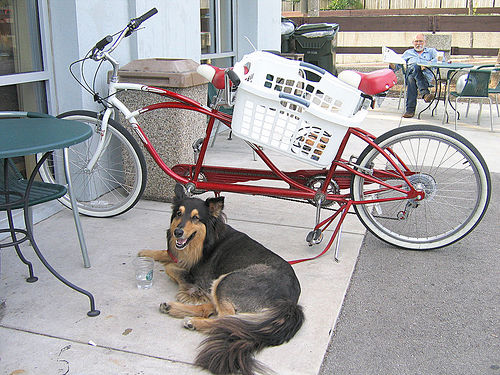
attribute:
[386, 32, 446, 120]
man — old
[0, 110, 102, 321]
table — green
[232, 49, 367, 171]
basket — white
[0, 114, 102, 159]
table — green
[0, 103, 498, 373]
sidewalk — light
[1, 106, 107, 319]
patio table — green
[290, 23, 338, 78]
can — green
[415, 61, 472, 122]
table — green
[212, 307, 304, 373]
dog tail — long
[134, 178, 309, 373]
collie — brown, black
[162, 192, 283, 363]
collie — black and brown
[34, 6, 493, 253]
bicycle — red and white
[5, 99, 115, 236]
table — patio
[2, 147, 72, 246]
chair — green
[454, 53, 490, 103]
chair — green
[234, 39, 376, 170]
basket — white